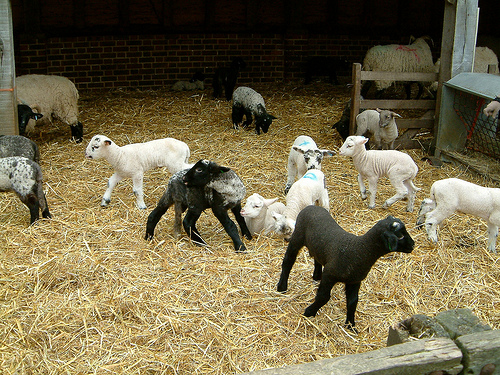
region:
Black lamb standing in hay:
[275, 202, 415, 329]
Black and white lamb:
[143, 156, 252, 253]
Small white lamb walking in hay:
[84, 132, 200, 212]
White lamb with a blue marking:
[272, 165, 332, 241]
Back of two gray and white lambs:
[0, 130, 52, 225]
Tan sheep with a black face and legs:
[12, 72, 84, 144]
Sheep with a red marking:
[359, 34, 440, 102]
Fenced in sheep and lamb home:
[0, 0, 498, 372]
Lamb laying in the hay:
[240, 188, 286, 240]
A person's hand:
[480, 93, 498, 124]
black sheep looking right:
[274, 196, 419, 336]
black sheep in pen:
[271, 198, 422, 330]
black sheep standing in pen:
[270, 197, 425, 329]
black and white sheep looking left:
[142, 157, 255, 257]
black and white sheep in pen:
[135, 147, 254, 259]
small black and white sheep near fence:
[221, 82, 280, 138]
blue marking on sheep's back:
[296, 167, 322, 186]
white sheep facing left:
[76, 121, 191, 212]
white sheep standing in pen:
[80, 127, 199, 221]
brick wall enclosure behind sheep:
[10, 3, 451, 110]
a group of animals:
[15, 92, 485, 329]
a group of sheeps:
[5, 55, 498, 331]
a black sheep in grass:
[278, 184, 436, 374]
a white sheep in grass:
[62, 119, 231, 201]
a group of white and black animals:
[83, 138, 480, 309]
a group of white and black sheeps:
[72, 103, 494, 298]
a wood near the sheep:
[349, 302, 491, 368]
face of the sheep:
[380, 212, 435, 269]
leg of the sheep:
[74, 172, 164, 209]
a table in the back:
[346, 33, 467, 163]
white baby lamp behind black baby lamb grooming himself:
[82, 128, 190, 220]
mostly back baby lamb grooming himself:
[139, 154, 253, 258]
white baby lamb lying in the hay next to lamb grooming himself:
[233, 185, 285, 244]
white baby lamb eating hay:
[273, 166, 332, 246]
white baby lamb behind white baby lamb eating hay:
[277, 134, 335, 186]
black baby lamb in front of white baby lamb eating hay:
[276, 196, 420, 331]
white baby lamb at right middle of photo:
[417, 167, 498, 264]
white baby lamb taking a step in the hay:
[337, 131, 422, 217]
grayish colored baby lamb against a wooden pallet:
[350, 103, 401, 163]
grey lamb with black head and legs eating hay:
[225, 80, 274, 137]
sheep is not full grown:
[229, 83, 281, 134]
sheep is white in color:
[335, 135, 420, 213]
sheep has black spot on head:
[83, 133, 195, 211]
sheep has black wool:
[271, 203, 416, 329]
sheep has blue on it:
[281, 129, 336, 190]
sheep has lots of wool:
[12, 72, 88, 144]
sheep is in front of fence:
[351, 105, 403, 151]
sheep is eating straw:
[226, 87, 281, 137]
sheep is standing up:
[228, 85, 281, 137]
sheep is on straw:
[227, 81, 279, 137]